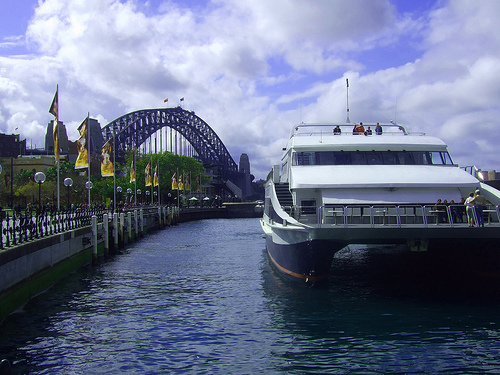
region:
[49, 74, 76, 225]
This is a pole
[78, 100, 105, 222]
This is a pole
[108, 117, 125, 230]
This is a pole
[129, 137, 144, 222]
This is a pole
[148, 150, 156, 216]
This is a pole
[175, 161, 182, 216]
This is a pole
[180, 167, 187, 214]
This is a pole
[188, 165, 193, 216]
This is a pole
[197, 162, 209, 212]
This is a pole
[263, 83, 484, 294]
ship in the water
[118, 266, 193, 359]
the body of water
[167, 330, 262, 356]
the water is calm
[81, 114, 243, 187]
arch of the bridge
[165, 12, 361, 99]
clouds in the sky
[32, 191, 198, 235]
bridge bordering the water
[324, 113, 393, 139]
people on the boat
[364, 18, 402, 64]
part of the sky is clear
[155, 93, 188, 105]
flags on the bridge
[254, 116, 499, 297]
a fancy boat sitting on the water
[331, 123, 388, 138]
people standing on the boat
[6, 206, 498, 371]
the water the boat is sitting on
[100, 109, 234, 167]
the blue bridge made out of steel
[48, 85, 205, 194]
a row of blue and yellow flags on a pole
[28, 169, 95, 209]
some street lights on the sidewalk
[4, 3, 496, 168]
a blue sky filled with a lot of white fluffy clouds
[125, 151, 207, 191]
a big tre with large green leaves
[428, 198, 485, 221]
more people standing on the boat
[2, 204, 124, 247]
a fence on the side of the road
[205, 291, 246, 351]
part of a water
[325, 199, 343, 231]
part of a fecne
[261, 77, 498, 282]
A white boat in the sea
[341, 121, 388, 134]
The group of people aboard a boat.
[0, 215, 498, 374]
The deep sea water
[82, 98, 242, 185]
A bridge in the background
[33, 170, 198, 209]
The street lighting next to the sea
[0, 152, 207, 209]
The green vegetation on the left.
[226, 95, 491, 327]
white and black boat on the river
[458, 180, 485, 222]
person standing on the boat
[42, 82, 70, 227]
flag on the pole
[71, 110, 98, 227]
flag on the pole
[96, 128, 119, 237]
flag on the pole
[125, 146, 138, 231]
flag on the pole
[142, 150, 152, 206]
flag on the pole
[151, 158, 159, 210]
flag on the pole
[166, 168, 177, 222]
flag on the pole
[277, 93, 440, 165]
People are standing on the deck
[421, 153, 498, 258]
A couple is hugging on the boat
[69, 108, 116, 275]
Yellow flag on the bridge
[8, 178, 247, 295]
Metal railing on the bridge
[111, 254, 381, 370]
The water is still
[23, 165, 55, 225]
The lamp is round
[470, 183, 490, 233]
The person is wearing a yellow shirt